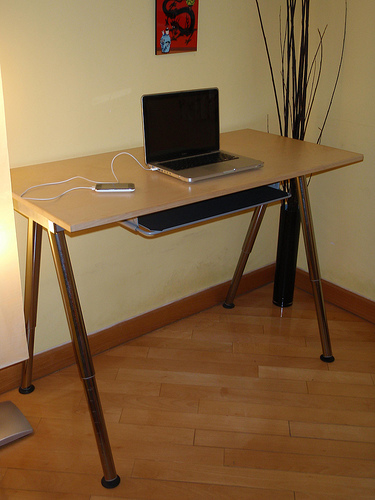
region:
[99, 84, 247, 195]
lap top sitting on table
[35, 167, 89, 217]
white cord from phone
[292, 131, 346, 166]
brown wooden table in corner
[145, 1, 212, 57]
red painting hanging from the wall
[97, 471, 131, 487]
black bottom of stand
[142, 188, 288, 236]
black key board for computer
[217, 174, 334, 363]
two bottom legs for table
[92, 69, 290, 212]
this is a laptop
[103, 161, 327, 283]
this is a keyboard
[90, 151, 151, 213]
this is a cellphone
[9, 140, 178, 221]
this is a cable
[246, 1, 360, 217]
this is a plant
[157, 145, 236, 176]
this is a keyboard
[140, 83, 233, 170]
this is a screen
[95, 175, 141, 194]
A white i phone on the table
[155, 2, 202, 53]
A picture of a dragon on the wall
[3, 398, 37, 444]
A silver object on the ground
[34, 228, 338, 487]
The legs of the desk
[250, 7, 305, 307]
A vase with sticks in it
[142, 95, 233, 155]
The screen of the laptop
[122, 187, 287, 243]
The keyboard section of the desk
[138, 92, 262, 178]
A laptop that is on the desk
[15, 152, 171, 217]
A phone that is connected by the charger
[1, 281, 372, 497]
A brown wooden floor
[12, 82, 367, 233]
A laptop computer on a table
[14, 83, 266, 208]
Cell phone plugged into a laptop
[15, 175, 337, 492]
Four legs of a table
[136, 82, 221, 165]
Laptop screen is turned off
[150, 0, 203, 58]
Red artwork on the wall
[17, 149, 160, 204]
A white electrical wire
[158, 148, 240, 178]
Black keys on laptop keyboard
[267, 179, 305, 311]
A long black pot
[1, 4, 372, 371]
The walls are white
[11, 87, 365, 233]
A laptop is on a table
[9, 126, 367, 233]
A brown wooden table surface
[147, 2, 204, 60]
Red artwork hanging on the wall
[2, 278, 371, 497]
The floor is brown and wooden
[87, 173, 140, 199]
A cell phone on the table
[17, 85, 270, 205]
Cell phone is plugged into a laptop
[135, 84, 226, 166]
A black laptop screen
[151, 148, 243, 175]
Black keys on a laptop keyboard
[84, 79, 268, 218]
a laptop on the desk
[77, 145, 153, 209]
a phon the desk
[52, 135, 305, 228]
a phone plugged into the computer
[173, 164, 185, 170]
a button on the keyboard